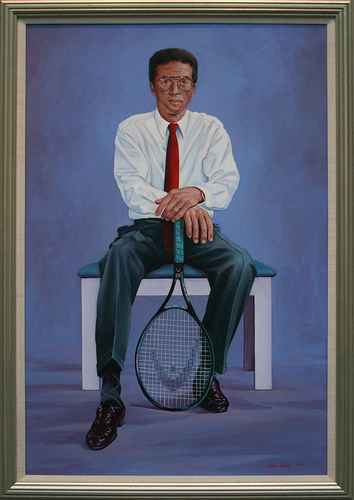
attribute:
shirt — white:
[110, 103, 243, 220]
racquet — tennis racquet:
[133, 216, 216, 410]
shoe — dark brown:
[84, 397, 126, 450]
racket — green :
[128, 178, 224, 419]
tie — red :
[163, 122, 179, 191]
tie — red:
[150, 128, 208, 198]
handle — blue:
[168, 215, 190, 274]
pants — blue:
[95, 215, 253, 375]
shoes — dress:
[79, 373, 220, 449]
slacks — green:
[95, 218, 256, 377]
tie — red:
[164, 122, 180, 258]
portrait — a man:
[63, 43, 256, 447]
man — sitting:
[73, 40, 261, 456]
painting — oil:
[4, 7, 345, 268]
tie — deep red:
[162, 124, 182, 196]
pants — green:
[94, 224, 150, 279]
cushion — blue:
[75, 250, 276, 277]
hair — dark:
[138, 37, 217, 65]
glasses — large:
[124, 57, 238, 107]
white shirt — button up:
[113, 105, 241, 218]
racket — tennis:
[140, 202, 222, 419]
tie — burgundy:
[166, 123, 179, 198]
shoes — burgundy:
[86, 401, 132, 448]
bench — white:
[76, 270, 278, 393]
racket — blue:
[126, 205, 216, 410]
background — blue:
[27, 27, 314, 387]